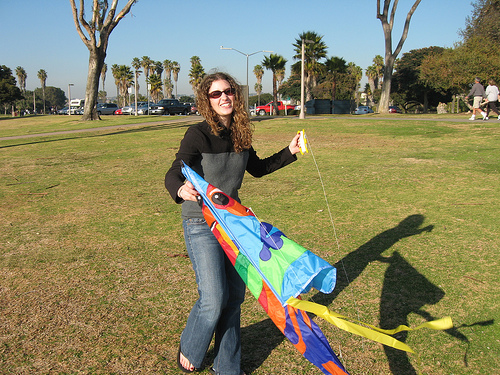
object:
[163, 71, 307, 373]
woman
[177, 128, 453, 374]
kite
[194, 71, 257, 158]
hair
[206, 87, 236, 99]
sunglasses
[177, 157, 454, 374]
brightly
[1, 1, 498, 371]
park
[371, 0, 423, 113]
trees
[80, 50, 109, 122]
trunks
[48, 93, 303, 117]
full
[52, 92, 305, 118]
lot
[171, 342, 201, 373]
sandals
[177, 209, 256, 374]
jeans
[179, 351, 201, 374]
foot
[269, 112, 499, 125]
path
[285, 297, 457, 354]
tail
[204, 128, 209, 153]
black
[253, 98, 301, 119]
parked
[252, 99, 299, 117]
truck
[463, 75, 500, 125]
two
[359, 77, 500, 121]
walking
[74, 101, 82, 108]
white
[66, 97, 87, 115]
truck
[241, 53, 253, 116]
poles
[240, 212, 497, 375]
shadow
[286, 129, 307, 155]
hand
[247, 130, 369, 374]
string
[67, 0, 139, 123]
trees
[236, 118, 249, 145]
brown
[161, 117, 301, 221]
top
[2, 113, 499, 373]
browish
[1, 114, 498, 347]
grass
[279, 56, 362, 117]
tree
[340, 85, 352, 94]
leaves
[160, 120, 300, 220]
sweater